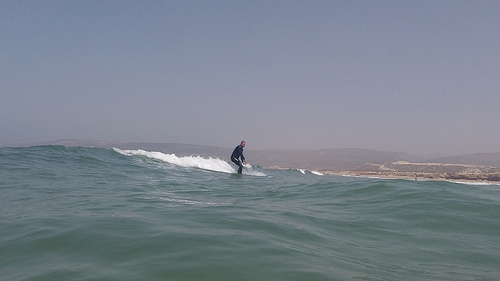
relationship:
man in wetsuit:
[229, 139, 256, 175] [232, 147, 246, 173]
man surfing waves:
[229, 139, 256, 175] [110, 136, 232, 178]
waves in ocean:
[110, 136, 232, 178] [3, 140, 499, 277]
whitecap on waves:
[115, 138, 235, 173] [110, 136, 232, 178]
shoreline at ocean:
[40, 142, 499, 192] [3, 140, 499, 277]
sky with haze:
[10, 4, 497, 156] [5, 4, 497, 166]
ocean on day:
[3, 140, 499, 277] [2, 5, 496, 275]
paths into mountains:
[373, 158, 483, 179] [108, 145, 499, 170]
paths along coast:
[373, 158, 483, 179] [240, 160, 500, 179]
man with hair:
[229, 140, 247, 175] [238, 140, 248, 145]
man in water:
[229, 140, 247, 175] [5, 145, 483, 276]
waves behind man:
[110, 136, 232, 178] [229, 140, 247, 175]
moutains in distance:
[111, 128, 498, 172] [11, 4, 499, 182]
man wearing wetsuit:
[229, 140, 247, 175] [232, 147, 246, 173]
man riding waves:
[229, 140, 247, 175] [110, 136, 232, 178]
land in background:
[108, 137, 498, 175] [3, 4, 499, 177]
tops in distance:
[108, 133, 500, 164] [11, 4, 499, 182]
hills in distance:
[107, 122, 499, 173] [11, 4, 499, 182]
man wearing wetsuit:
[229, 139, 256, 175] [232, 147, 246, 173]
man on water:
[229, 139, 256, 175] [5, 145, 483, 276]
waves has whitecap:
[110, 136, 232, 178] [115, 138, 235, 173]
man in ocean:
[229, 139, 256, 175] [3, 140, 499, 277]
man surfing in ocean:
[229, 139, 256, 175] [3, 140, 499, 277]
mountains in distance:
[414, 151, 499, 167] [11, 4, 499, 182]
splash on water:
[295, 163, 326, 179] [5, 145, 483, 276]